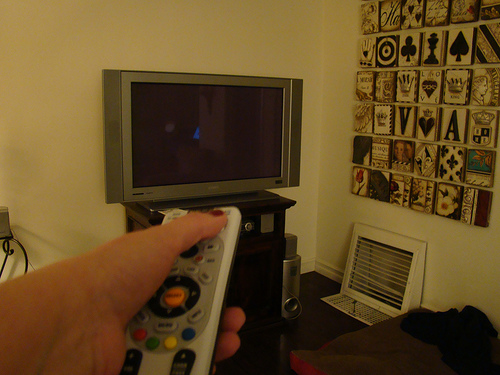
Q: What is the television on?
A: A stand.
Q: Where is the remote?
A: In a person's hand.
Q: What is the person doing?
A: Turning on their TV.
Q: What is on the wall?
A: Artwork.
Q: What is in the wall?
A: A metal vent.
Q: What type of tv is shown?
A: Older flat screen.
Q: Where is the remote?
A: Person's hand.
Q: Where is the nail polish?
A: Thumb nail.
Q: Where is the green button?
A: Between the red and yellow button.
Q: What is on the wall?
A: Decorative tiles.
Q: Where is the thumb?
A: Power button on remote.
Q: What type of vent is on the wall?
A: Heat.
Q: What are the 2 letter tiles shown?
A: V, A.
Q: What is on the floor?
A: Vent.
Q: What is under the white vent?
A: A brown hardwood floor.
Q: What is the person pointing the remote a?
A: A flat screen TV.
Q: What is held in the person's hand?
A: A remote control.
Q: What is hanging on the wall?
A: Artwork with playing cards on it.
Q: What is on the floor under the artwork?
A: A white vent.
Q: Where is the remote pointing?
A: At a television.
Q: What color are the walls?
A: White.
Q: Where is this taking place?
A: Living room.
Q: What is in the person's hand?
A: Remote Control.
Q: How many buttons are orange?
A: 1.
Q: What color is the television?
A: Silver.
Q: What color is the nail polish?
A: Red.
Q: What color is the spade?
A: Black.